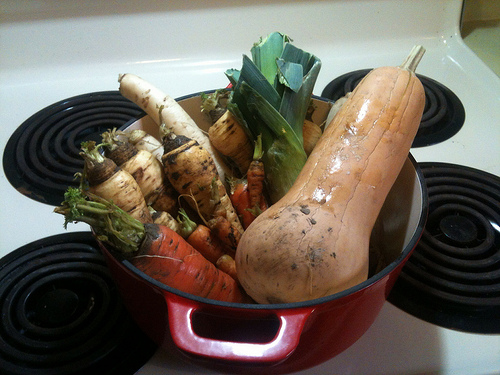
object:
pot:
[62, 73, 435, 374]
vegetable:
[47, 20, 442, 315]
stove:
[9, 85, 121, 197]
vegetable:
[221, 26, 328, 190]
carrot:
[68, 202, 237, 298]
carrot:
[243, 142, 265, 209]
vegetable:
[229, 38, 436, 313]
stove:
[2, 0, 500, 371]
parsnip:
[81, 141, 157, 204]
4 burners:
[3, 59, 500, 372]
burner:
[418, 155, 500, 317]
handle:
[154, 289, 312, 368]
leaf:
[48, 179, 148, 256]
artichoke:
[299, 104, 331, 140]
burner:
[2, 231, 130, 366]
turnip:
[148, 120, 251, 238]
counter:
[461, 3, 499, 61]